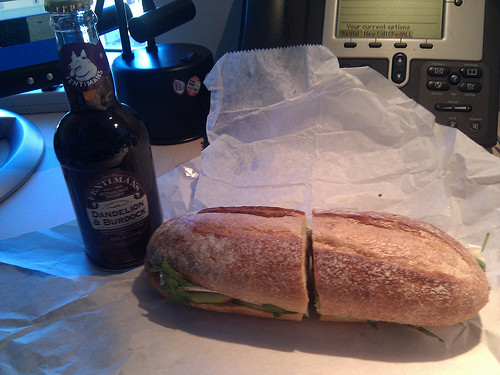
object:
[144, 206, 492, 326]
sandwich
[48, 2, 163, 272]
bottle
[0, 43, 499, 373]
wrapper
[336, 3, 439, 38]
screen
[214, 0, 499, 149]
phone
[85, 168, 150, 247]
label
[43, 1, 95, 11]
cap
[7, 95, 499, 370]
desk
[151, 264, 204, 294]
lettuce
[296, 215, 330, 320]
line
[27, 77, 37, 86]
knob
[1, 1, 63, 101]
monitor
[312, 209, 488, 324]
bread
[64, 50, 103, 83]
dog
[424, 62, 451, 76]
buttons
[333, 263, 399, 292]
flour